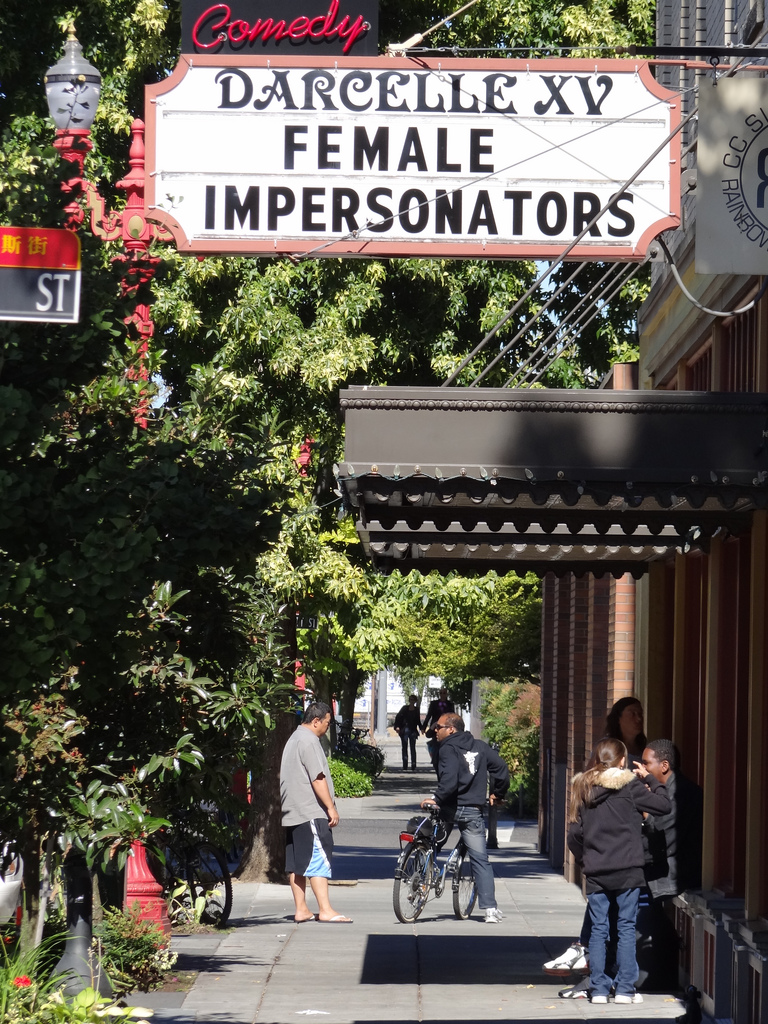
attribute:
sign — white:
[144, 54, 682, 256]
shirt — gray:
[281, 724, 338, 826]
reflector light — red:
[397, 832, 412, 841]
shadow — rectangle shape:
[361, 931, 666, 986]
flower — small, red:
[9, 959, 51, 1001]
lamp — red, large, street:
[49, 14, 147, 461]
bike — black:
[368, 775, 493, 918]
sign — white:
[134, 57, 725, 276]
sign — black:
[151, 4, 380, 59]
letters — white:
[1, 270, 74, 330]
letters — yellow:
[3, 224, 75, 254]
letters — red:
[183, 3, 381, 50]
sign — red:
[6, 225, 74, 262]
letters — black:
[320, 524, 667, 623]